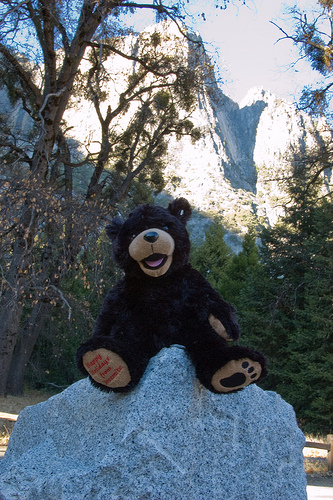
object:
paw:
[210, 345, 270, 412]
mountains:
[154, 11, 318, 209]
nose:
[142, 221, 158, 244]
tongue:
[143, 254, 166, 274]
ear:
[167, 196, 194, 218]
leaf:
[285, 333, 328, 406]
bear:
[77, 183, 265, 431]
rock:
[7, 332, 317, 494]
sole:
[74, 343, 133, 392]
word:
[101, 363, 126, 390]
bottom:
[79, 347, 134, 388]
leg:
[73, 312, 159, 394]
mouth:
[136, 249, 171, 271]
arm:
[194, 279, 242, 326]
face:
[120, 206, 180, 274]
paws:
[74, 346, 264, 393]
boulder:
[1, 336, 309, 497]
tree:
[216, 210, 269, 366]